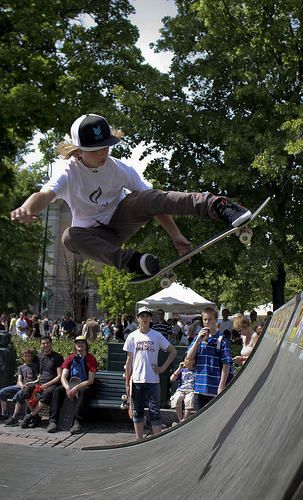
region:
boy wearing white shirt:
[48, 121, 214, 262]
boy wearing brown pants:
[59, 156, 171, 262]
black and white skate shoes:
[208, 201, 268, 232]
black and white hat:
[59, 124, 124, 152]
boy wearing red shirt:
[60, 335, 101, 397]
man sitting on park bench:
[29, 336, 54, 425]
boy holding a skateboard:
[122, 318, 167, 421]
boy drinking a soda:
[190, 306, 235, 397]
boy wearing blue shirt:
[192, 304, 227, 398]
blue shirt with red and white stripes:
[192, 334, 227, 391]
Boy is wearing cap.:
[10, 112, 274, 306]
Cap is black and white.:
[11, 103, 293, 298]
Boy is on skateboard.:
[8, 101, 282, 300]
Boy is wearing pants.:
[8, 112, 287, 308]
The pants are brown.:
[8, 109, 285, 297]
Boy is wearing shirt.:
[11, 103, 286, 315]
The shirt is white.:
[8, 100, 287, 306]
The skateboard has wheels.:
[8, 113, 282, 306]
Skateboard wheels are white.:
[8, 119, 288, 297]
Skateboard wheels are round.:
[6, 107, 287, 292]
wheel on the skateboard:
[155, 277, 178, 289]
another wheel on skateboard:
[236, 230, 257, 243]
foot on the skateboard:
[131, 254, 169, 275]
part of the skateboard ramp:
[73, 464, 181, 486]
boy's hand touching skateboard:
[166, 228, 201, 254]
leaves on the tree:
[216, 45, 268, 96]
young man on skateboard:
[6, 110, 277, 281]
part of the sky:
[137, 3, 164, 13]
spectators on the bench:
[0, 329, 99, 431]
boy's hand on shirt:
[146, 356, 163, 375]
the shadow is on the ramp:
[215, 332, 296, 477]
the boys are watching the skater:
[112, 303, 230, 403]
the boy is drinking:
[182, 305, 231, 392]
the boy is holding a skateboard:
[119, 305, 173, 426]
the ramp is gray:
[252, 420, 279, 460]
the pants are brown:
[125, 192, 218, 224]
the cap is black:
[70, 116, 130, 148]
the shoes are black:
[209, 193, 252, 230]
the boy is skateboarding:
[8, 96, 284, 293]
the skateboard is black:
[125, 226, 273, 274]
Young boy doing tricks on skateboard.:
[9, 113, 280, 288]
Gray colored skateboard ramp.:
[137, 310, 300, 499]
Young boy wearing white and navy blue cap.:
[67, 113, 124, 153]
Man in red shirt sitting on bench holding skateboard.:
[46, 336, 104, 432]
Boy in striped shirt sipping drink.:
[186, 306, 237, 412]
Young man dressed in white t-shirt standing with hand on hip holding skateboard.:
[118, 305, 176, 436]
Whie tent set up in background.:
[135, 276, 225, 327]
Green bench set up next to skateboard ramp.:
[97, 364, 131, 425]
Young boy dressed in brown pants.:
[62, 187, 230, 272]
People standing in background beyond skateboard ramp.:
[13, 304, 103, 341]